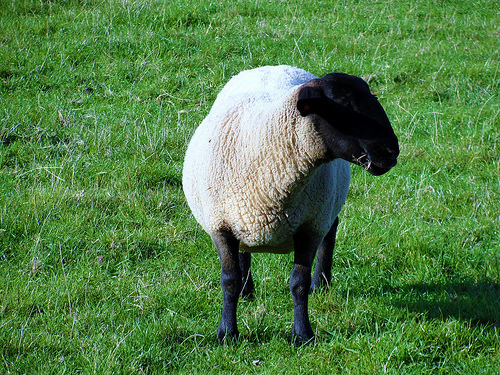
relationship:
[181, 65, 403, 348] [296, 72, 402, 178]
sheep with head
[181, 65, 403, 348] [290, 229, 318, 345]
sheep with leg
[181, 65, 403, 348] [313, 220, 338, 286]
sheep with leg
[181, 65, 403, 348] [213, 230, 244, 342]
sheep with leg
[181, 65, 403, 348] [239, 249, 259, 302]
sheep with leg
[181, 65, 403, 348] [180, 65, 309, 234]
sheep with body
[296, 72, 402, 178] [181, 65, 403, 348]
head of sheep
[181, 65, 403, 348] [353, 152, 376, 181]
sheep eats grass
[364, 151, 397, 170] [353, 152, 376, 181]
mouth of grass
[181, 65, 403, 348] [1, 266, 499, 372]
sheep stands on grass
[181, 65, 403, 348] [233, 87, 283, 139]
sheep has hair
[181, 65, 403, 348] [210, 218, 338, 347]
sheep stands on legs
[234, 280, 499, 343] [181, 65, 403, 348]
shadow of sheep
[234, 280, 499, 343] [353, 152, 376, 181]
shadow on grass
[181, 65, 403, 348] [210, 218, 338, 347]
sheep has legs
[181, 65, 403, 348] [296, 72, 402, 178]
sheep has a head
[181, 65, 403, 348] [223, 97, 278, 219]
sheep has wool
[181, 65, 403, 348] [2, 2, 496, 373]
sheep in field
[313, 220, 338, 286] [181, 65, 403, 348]
leg of a sheep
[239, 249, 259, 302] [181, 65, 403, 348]
leg of a sheep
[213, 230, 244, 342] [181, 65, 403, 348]
leg of a sheep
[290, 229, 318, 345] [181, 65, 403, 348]
leg of a sheep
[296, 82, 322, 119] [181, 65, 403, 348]
ear of a sheep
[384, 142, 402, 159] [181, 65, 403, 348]
nose of a sheep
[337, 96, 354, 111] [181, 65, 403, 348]
eye of a sheep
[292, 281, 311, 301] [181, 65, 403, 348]
knee of a sheep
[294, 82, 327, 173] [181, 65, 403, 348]
neck of a sheep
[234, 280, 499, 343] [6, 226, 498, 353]
shadow on ground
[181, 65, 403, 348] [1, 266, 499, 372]
sheep on grass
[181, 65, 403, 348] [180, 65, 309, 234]
sheep has a body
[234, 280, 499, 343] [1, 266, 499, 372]
shadow on grass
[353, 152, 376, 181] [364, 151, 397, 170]
grass in mouth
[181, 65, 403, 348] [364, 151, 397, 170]
sheep has a mouth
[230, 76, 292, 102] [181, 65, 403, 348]
sun shining on sheep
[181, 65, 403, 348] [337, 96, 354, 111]
sheep has an eye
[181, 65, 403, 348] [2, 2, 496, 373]
sheep standing in field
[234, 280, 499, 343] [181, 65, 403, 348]
shadow casty by a sheep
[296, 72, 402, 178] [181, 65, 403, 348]
head of a sheep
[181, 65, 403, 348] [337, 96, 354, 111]
sheep has a right eye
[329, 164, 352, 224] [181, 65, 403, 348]
back of a sheep